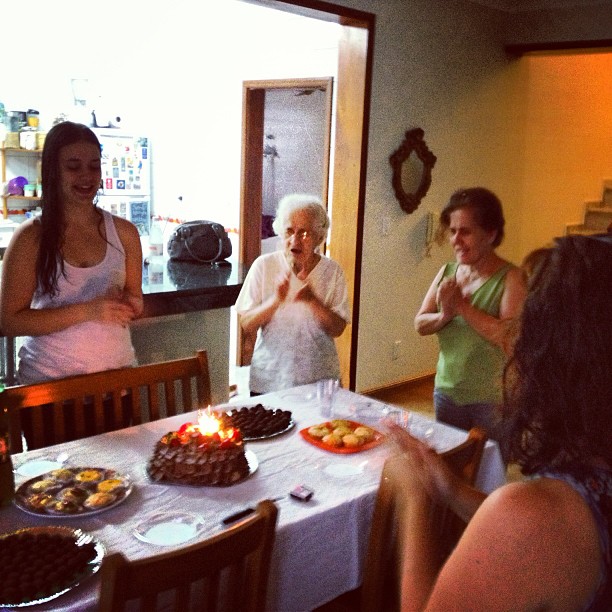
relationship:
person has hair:
[236, 194, 350, 398] [267, 188, 333, 242]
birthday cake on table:
[145, 404, 250, 487] [0, 367, 519, 604]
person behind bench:
[0, 122, 143, 454] [0, 347, 214, 465]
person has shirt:
[413, 186, 526, 475] [420, 245, 526, 416]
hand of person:
[287, 267, 314, 307] [236, 194, 350, 398]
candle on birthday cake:
[184, 398, 230, 444] [145, 404, 250, 487]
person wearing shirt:
[0, 122, 143, 454] [9, 207, 145, 389]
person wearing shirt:
[413, 186, 526, 475] [426, 251, 532, 420]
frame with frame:
[388, 127, 438, 214] [376, 111, 443, 226]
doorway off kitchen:
[222, 61, 345, 373] [0, 2, 370, 448]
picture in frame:
[401, 150, 424, 194] [388, 127, 436, 213]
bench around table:
[0, 348, 212, 453] [2, 379, 499, 609]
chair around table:
[99, 500, 279, 609] [2, 379, 499, 609]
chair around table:
[361, 425, 492, 610] [2, 379, 499, 609]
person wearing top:
[413, 186, 526, 475] [430, 252, 513, 399]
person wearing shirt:
[236, 194, 350, 398] [231, 249, 351, 388]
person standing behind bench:
[0, 122, 143, 454] [2, 338, 220, 445]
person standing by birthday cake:
[236, 194, 350, 398] [150, 412, 254, 488]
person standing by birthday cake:
[413, 186, 526, 475] [150, 412, 254, 488]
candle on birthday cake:
[185, 398, 228, 440] [146, 429, 256, 490]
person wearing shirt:
[0, 122, 143, 454] [14, 207, 140, 389]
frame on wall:
[388, 127, 438, 214] [351, 5, 509, 395]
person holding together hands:
[413, 186, 526, 475] [432, 265, 473, 332]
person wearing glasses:
[236, 194, 350, 398] [278, 221, 330, 249]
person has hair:
[0, 122, 143, 454] [25, 117, 118, 299]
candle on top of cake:
[185, 398, 228, 440] [150, 426, 257, 487]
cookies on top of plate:
[313, 417, 376, 447] [298, 413, 387, 460]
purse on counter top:
[168, 215, 235, 265] [134, 253, 254, 323]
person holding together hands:
[413, 186, 526, 475] [423, 267, 473, 329]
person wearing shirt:
[413, 186, 526, 475] [426, 252, 518, 401]